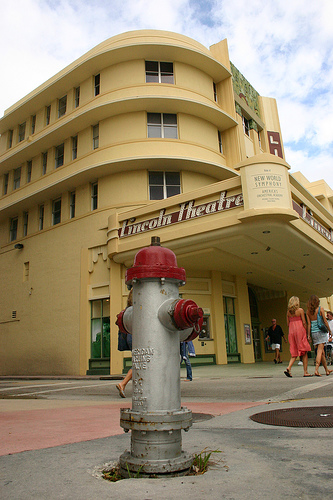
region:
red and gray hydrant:
[117, 234, 205, 480]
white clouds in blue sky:
[11, 14, 41, 43]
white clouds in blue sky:
[11, 17, 22, 45]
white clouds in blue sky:
[8, 47, 45, 72]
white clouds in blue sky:
[10, 7, 68, 44]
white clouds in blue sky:
[77, 8, 105, 28]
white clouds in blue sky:
[195, 7, 218, 39]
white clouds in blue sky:
[261, 12, 320, 46]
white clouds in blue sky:
[240, 30, 271, 73]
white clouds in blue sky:
[273, 49, 303, 89]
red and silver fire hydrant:
[102, 231, 216, 480]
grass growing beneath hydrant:
[106, 449, 212, 482]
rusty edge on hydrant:
[114, 412, 155, 429]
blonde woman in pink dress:
[284, 296, 314, 382]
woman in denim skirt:
[304, 293, 332, 380]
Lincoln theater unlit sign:
[110, 183, 244, 242]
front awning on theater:
[101, 150, 332, 328]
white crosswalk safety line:
[254, 373, 332, 409]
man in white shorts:
[262, 311, 286, 364]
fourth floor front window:
[137, 51, 177, 92]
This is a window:
[142, 169, 194, 208]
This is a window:
[146, 105, 181, 138]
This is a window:
[143, 53, 180, 83]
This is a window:
[85, 67, 104, 99]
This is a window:
[85, 118, 103, 152]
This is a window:
[84, 179, 107, 219]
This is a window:
[64, 187, 80, 221]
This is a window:
[66, 130, 86, 164]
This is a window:
[66, 77, 85, 111]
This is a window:
[55, 92, 68, 122]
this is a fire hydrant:
[96, 226, 241, 496]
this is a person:
[176, 341, 203, 389]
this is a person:
[257, 308, 284, 370]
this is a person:
[282, 279, 311, 396]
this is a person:
[306, 286, 329, 392]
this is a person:
[325, 309, 330, 345]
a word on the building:
[114, 208, 171, 238]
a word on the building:
[170, 187, 246, 218]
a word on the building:
[296, 200, 329, 253]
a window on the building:
[45, 194, 73, 235]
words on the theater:
[111, 188, 248, 243]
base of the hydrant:
[112, 433, 204, 485]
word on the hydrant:
[123, 341, 157, 373]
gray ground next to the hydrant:
[236, 446, 269, 481]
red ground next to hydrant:
[32, 412, 70, 440]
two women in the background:
[275, 291, 332, 342]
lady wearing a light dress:
[282, 294, 306, 370]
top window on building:
[135, 49, 189, 91]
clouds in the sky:
[255, 10, 308, 58]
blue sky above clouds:
[187, 2, 219, 27]